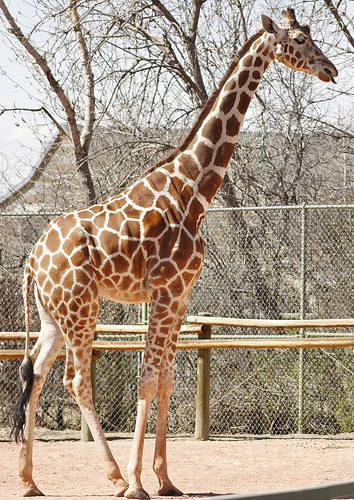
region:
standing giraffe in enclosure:
[16, 6, 336, 362]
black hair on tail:
[6, 348, 38, 448]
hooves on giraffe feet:
[127, 480, 187, 498]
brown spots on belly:
[108, 254, 144, 295]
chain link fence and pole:
[268, 199, 339, 280]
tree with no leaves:
[103, 16, 212, 97]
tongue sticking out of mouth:
[320, 62, 344, 88]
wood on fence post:
[183, 309, 226, 443]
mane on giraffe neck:
[207, 43, 248, 97]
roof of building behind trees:
[44, 115, 158, 173]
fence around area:
[0, 194, 351, 441]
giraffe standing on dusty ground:
[3, 421, 332, 497]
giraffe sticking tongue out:
[242, 5, 340, 92]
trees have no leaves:
[3, 5, 160, 147]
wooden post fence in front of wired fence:
[0, 308, 352, 442]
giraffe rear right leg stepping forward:
[18, 213, 199, 498]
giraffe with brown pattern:
[4, 9, 343, 348]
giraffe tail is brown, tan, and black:
[4, 231, 109, 452]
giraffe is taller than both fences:
[6, 7, 337, 498]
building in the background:
[0, 86, 352, 375]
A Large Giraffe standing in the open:
[1, 6, 338, 497]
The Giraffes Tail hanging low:
[6, 243, 43, 443]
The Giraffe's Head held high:
[255, 0, 348, 99]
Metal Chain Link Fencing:
[207, 199, 347, 307]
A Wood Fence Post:
[184, 308, 213, 437]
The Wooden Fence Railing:
[189, 306, 349, 348]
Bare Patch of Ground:
[187, 437, 330, 477]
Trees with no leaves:
[4, 0, 190, 126]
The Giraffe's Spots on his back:
[132, 199, 168, 238]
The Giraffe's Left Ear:
[251, 6, 287, 44]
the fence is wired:
[281, 401, 292, 417]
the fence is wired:
[270, 412, 278, 421]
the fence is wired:
[267, 400, 276, 418]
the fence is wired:
[261, 405, 274, 427]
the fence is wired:
[282, 416, 290, 429]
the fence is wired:
[280, 408, 290, 431]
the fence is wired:
[273, 401, 281, 424]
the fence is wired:
[255, 425, 261, 433]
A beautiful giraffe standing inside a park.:
[7, 5, 339, 499]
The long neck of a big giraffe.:
[135, 38, 276, 234]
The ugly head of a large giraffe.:
[253, 4, 336, 82]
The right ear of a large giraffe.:
[259, 12, 288, 37]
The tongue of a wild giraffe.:
[324, 67, 338, 84]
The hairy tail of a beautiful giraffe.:
[1, 260, 35, 445]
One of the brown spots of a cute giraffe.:
[140, 205, 167, 239]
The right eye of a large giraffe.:
[291, 34, 307, 45]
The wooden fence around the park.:
[0, 311, 352, 440]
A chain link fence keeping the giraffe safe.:
[0, 202, 353, 432]